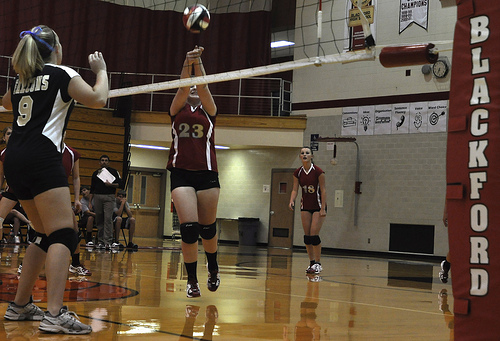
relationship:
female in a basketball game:
[0, 24, 109, 336] [4, 3, 497, 339]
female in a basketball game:
[289, 146, 329, 274] [4, 3, 497, 339]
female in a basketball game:
[167, 45, 221, 298] [4, 3, 497, 339]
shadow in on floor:
[177, 298, 221, 338] [1, 246, 498, 338]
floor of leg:
[1, 246, 498, 338] [307, 210, 328, 265]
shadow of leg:
[177, 298, 221, 338] [194, 188, 221, 263]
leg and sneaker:
[194, 188, 221, 263] [308, 258, 325, 276]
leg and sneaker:
[170, 186, 202, 277] [181, 280, 201, 301]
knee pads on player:
[171, 215, 230, 247] [150, 34, 233, 286]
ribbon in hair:
[16, 27, 46, 42] [11, 36, 39, 81]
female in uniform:
[0, 24, 109, 336] [2, 63, 82, 201]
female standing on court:
[289, 146, 329, 274] [90, 242, 465, 337]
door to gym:
[136, 172, 158, 234] [1, 0, 498, 338]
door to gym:
[121, 172, 136, 246] [1, 0, 498, 338]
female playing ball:
[291, 145, 338, 280] [182, 4, 210, 34]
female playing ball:
[167, 47, 224, 294] [182, 4, 210, 34]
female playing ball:
[0, 24, 109, 336] [182, 4, 210, 34]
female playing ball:
[26, 122, 93, 277] [182, 4, 210, 34]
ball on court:
[182, 4, 210, 34] [2, 233, 497, 339]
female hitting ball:
[167, 45, 221, 298] [169, 5, 222, 37]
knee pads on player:
[180, 219, 218, 244] [146, 28, 278, 291]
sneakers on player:
[156, 270, 223, 307] [152, 33, 296, 296]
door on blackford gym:
[135, 174, 161, 238] [0, 0, 500, 341]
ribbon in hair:
[20, 26, 55, 51] [10, 22, 52, 77]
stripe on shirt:
[197, 120, 218, 169] [158, 102, 247, 190]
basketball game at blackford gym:
[0, 3, 328, 334] [74, 57, 295, 257]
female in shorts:
[289, 146, 329, 274] [299, 191, 321, 215]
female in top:
[289, 146, 329, 274] [283, 168, 325, 206]